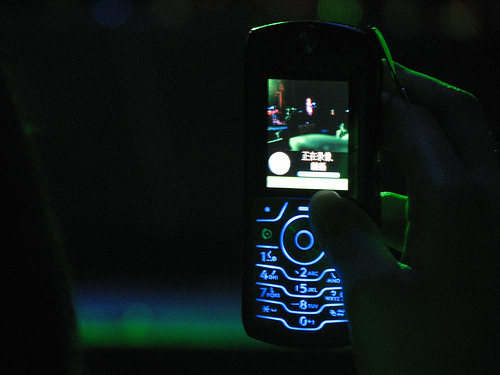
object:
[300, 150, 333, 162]
logo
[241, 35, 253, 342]
phoneedge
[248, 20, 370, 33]
phoneedge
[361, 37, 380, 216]
phoneedge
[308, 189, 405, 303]
finger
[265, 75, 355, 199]
screen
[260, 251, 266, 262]
number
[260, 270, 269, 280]
number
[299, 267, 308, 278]
number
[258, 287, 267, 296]
number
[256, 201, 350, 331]
keypad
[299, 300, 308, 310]
eight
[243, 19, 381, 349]
cell phone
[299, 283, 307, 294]
number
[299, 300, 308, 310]
number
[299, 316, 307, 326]
number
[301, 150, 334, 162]
asian text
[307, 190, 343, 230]
nail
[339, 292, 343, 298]
number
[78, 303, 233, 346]
stripe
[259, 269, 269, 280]
4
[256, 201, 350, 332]
button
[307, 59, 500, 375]
hand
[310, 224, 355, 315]
edge